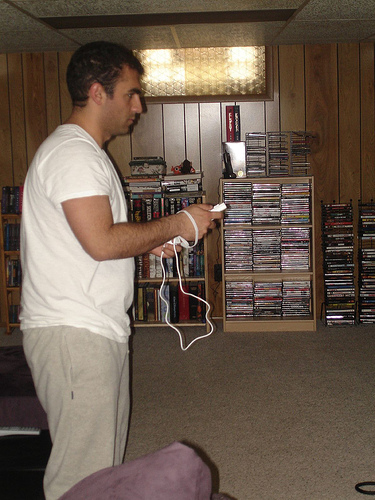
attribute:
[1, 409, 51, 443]
remote controller — white 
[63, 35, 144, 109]
hair — short , black 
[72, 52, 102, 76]
hair — brown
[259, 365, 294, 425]
carpet — light brown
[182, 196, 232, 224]
controller — white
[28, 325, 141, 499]
pants — grey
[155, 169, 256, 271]
controller — white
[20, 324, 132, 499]
sweatpants — gray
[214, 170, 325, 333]
case — brown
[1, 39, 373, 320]
wall — dark brown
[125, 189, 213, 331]
bookshelf — brown 